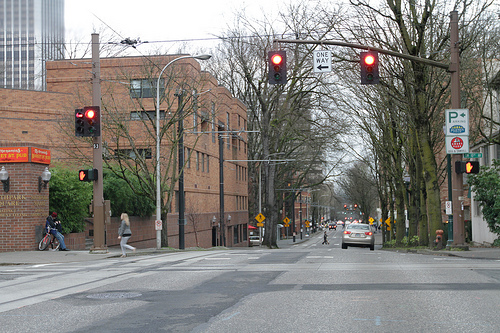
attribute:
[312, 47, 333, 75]
sign — one way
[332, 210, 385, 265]
car — silver